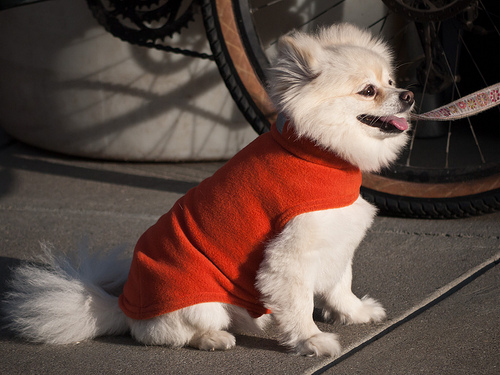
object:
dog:
[0, 21, 418, 359]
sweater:
[115, 120, 363, 320]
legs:
[252, 228, 340, 357]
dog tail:
[4, 222, 130, 347]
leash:
[409, 81, 498, 123]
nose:
[396, 90, 415, 106]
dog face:
[314, 46, 416, 150]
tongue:
[380, 115, 408, 132]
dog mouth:
[354, 112, 412, 137]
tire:
[201, 0, 498, 219]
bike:
[0, 0, 499, 221]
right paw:
[196, 328, 237, 351]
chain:
[93, 7, 215, 63]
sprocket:
[89, 0, 204, 42]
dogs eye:
[354, 83, 376, 100]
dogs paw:
[291, 330, 344, 360]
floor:
[0, 153, 497, 374]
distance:
[0, 0, 499, 161]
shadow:
[0, 19, 247, 195]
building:
[0, 0, 386, 165]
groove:
[301, 251, 499, 375]